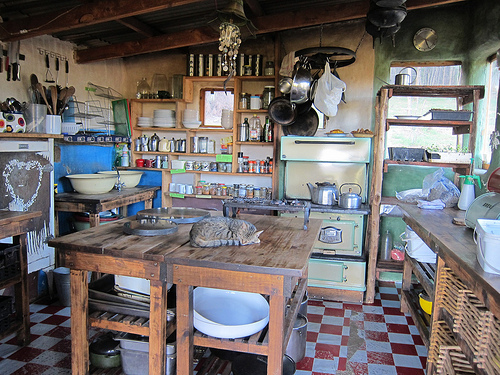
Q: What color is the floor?
A: Red and white.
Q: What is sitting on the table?
A: A cat.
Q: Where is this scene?
A: In a kitchen.